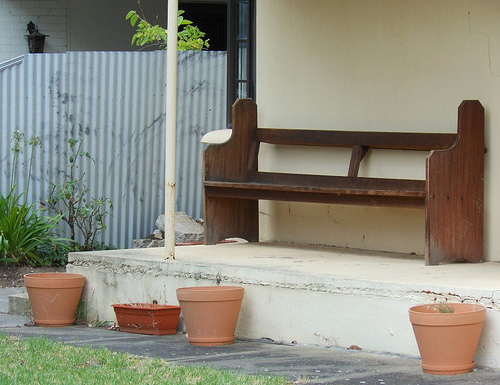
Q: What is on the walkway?
A: Ceramic pots.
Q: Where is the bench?
A: On a porch.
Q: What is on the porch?
A: A bench.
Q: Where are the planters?
A: On the sidewalk.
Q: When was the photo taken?
A: During daylight hours.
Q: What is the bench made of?
A: Wood.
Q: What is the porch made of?
A: Cement.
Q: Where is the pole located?
A: On the porch.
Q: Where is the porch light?
A: On the brick wall.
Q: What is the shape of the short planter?
A: Rectangular.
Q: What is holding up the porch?
A: White pole.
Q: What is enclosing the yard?
A: Fence.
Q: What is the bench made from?
A: Wood.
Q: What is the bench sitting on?
A: Concrete pad.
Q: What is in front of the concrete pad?
A: Flower pots.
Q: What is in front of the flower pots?
A: Green grass.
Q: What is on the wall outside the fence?
A: Light.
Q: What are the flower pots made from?
A: Terracotta.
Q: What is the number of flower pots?
A: Three.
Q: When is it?
A: Day time.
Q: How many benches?
A: 1.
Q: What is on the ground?
A: Pots.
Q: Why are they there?
A: To plant.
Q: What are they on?
A: Sidewalk.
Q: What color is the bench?
A: Brown.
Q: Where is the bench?
A: Under the porch.